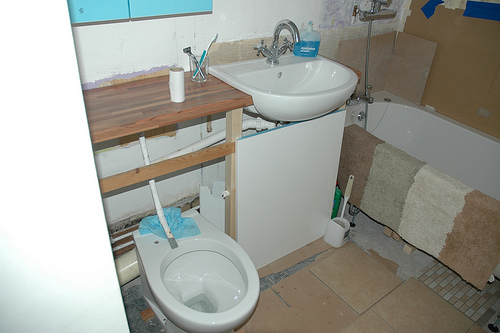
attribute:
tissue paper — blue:
[141, 209, 201, 237]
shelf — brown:
[70, 57, 257, 135]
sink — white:
[206, 52, 358, 122]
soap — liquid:
[291, 19, 326, 67]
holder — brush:
[324, 212, 351, 239]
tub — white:
[355, 99, 499, 200]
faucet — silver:
[254, 20, 299, 64]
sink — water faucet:
[209, 33, 380, 140]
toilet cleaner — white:
[320, 171, 365, 254]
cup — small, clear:
[191, 56, 207, 85]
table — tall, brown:
[105, 62, 237, 174]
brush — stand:
[192, 31, 223, 81]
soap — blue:
[290, 20, 319, 59]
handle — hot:
[241, 36, 296, 76]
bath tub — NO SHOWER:
[337, 89, 498, 285]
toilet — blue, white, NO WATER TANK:
[128, 209, 260, 331]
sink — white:
[205, 49, 364, 129]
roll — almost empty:
[166, 65, 194, 112]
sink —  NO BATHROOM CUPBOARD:
[210, 43, 356, 106]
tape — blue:
[417, 2, 442, 18]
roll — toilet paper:
[168, 65, 187, 103]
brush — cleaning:
[328, 174, 383, 246]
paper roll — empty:
[163, 65, 205, 101]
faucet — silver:
[260, 18, 326, 81]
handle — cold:
[278, 38, 298, 54]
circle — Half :
[264, 58, 337, 94]